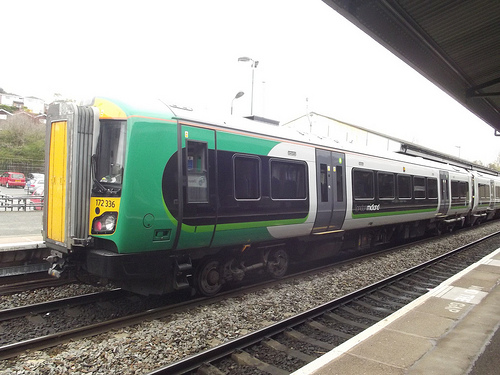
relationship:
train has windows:
[27, 95, 499, 303] [266, 156, 309, 207]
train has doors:
[27, 95, 499, 303] [314, 139, 350, 243]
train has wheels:
[27, 95, 499, 303] [182, 239, 296, 302]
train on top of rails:
[27, 95, 499, 303] [1, 267, 160, 358]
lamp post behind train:
[232, 50, 268, 114] [27, 95, 499, 303]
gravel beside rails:
[5, 315, 231, 374] [1, 267, 160, 358]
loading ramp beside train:
[298, 268, 499, 368] [27, 95, 499, 303]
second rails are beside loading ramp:
[122, 228, 499, 374] [298, 268, 499, 368]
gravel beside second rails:
[5, 315, 231, 374] [122, 228, 499, 374]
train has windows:
[27, 95, 499, 303] [94, 115, 125, 192]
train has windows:
[27, 95, 499, 303] [346, 165, 443, 207]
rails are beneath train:
[1, 267, 160, 358] [27, 95, 499, 303]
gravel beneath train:
[5, 315, 231, 374] [27, 95, 499, 303]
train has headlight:
[27, 95, 499, 303] [89, 210, 115, 239]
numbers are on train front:
[92, 196, 118, 213] [35, 87, 154, 290]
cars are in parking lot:
[0, 166, 47, 213] [4, 187, 42, 220]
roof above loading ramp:
[314, 4, 499, 132] [298, 268, 499, 368]